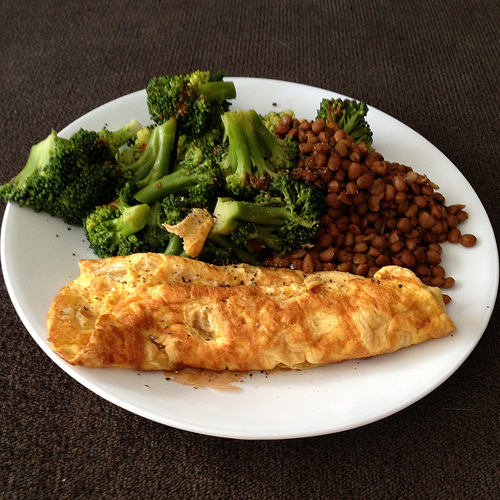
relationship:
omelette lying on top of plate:
[45, 253, 458, 372] [2, 74, 484, 442]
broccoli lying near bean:
[206, 177, 320, 260] [343, 231, 354, 249]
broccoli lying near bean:
[82, 180, 150, 259] [313, 151, 327, 169]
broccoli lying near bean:
[1, 128, 121, 226] [280, 113, 293, 127]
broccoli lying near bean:
[145, 66, 236, 140] [382, 181, 395, 201]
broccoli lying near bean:
[212, 108, 301, 198] [412, 194, 430, 209]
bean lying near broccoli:
[280, 113, 293, 127] [142, 65, 237, 135]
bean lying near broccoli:
[271, 113, 476, 303] [212, 108, 301, 198]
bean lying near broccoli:
[271, 113, 476, 303] [131, 142, 228, 211]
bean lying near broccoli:
[271, 113, 476, 303] [206, 177, 320, 260]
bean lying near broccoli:
[271, 113, 476, 303] [81, 182, 155, 258]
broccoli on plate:
[317, 97, 367, 142] [2, 74, 484, 442]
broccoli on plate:
[206, 177, 320, 260] [2, 74, 484, 442]